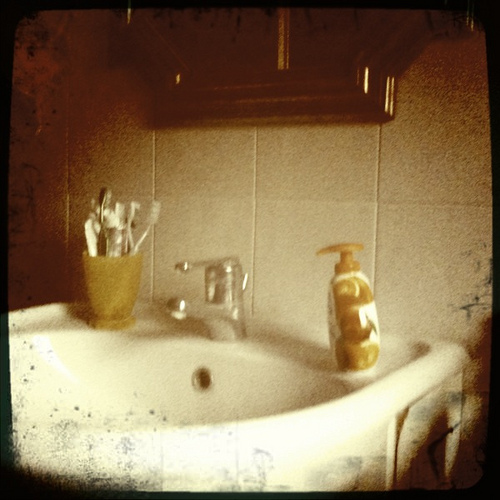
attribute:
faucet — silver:
[158, 253, 251, 344]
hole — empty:
[190, 364, 213, 396]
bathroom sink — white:
[0, 293, 471, 495]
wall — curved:
[257, 138, 471, 218]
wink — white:
[43, 291, 403, 495]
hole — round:
[191, 365, 213, 392]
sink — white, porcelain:
[8, 297, 472, 497]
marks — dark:
[445, 246, 499, 335]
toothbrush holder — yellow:
[78, 249, 145, 331]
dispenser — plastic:
[312, 240, 359, 267]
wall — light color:
[10, 12, 492, 362]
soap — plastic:
[310, 235, 404, 390]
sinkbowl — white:
[17, 333, 352, 427]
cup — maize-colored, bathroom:
[80, 249, 145, 331]